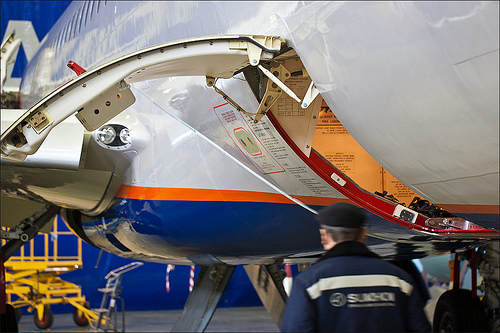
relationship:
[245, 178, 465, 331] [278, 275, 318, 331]
person has arm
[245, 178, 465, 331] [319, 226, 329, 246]
person has ear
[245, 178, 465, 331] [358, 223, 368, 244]
person has ear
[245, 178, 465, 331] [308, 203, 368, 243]
person has hair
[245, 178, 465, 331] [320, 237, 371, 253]
person has neck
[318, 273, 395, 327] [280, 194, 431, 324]
back of person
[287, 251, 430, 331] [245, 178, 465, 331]
jacket of person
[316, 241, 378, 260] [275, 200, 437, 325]
collar of a person